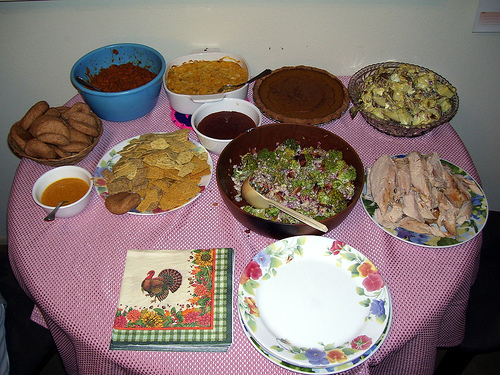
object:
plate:
[93, 131, 489, 374]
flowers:
[231, 139, 357, 223]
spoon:
[41, 196, 70, 223]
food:
[6, 42, 488, 249]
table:
[7, 75, 481, 375]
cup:
[31, 165, 94, 217]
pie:
[251, 65, 353, 128]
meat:
[364, 149, 485, 238]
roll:
[9, 101, 99, 159]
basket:
[7, 106, 103, 166]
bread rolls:
[6, 100, 100, 160]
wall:
[0, 0, 498, 224]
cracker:
[102, 127, 206, 215]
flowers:
[237, 237, 391, 374]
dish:
[347, 62, 462, 139]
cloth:
[6, 74, 481, 375]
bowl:
[6, 43, 490, 375]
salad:
[229, 138, 356, 223]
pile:
[329, 334, 379, 371]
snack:
[100, 129, 210, 215]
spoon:
[240, 177, 329, 233]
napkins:
[108, 246, 233, 352]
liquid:
[198, 110, 256, 140]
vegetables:
[349, 67, 453, 127]